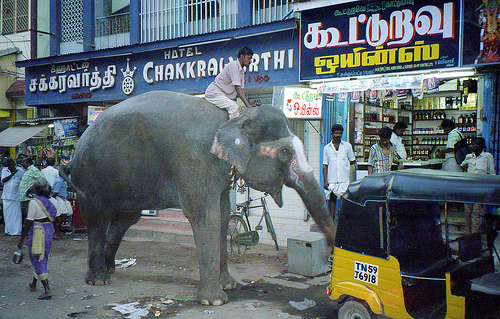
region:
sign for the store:
[304, 0, 461, 67]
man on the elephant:
[69, 35, 326, 301]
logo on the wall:
[20, 66, 225, 85]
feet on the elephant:
[186, 264, 251, 304]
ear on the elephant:
[196, 123, 251, 178]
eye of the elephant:
[277, 140, 303, 178]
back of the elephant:
[125, 86, 208, 113]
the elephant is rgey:
[185, 174, 221, 201]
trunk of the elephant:
[290, 186, 337, 238]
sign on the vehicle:
[350, 260, 384, 285]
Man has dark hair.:
[236, 45, 256, 65]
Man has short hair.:
[238, 46, 264, 68]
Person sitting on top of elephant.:
[182, 50, 253, 137]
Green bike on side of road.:
[222, 182, 290, 254]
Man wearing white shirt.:
[321, 148, 353, 174]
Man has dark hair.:
[327, 117, 347, 139]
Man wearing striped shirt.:
[368, 140, 396, 178]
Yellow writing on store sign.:
[325, 43, 428, 62]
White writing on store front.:
[31, 73, 166, 91]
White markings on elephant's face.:
[287, 131, 338, 201]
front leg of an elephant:
[172, 158, 229, 308]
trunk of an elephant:
[292, 142, 341, 264]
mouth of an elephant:
[270, 175, 299, 206]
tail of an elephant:
[56, 154, 92, 211]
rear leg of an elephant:
[73, 182, 118, 289]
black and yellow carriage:
[324, 168, 493, 316]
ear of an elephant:
[212, 114, 255, 176]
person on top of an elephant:
[207, 50, 258, 123]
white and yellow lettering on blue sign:
[302, 7, 470, 65]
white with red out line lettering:
[293, 7, 455, 74]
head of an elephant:
[210, 99, 310, 209]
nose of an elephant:
[295, 163, 356, 250]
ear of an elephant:
[180, 112, 248, 177]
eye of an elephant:
[269, 135, 297, 160]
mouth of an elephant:
[269, 171, 294, 202]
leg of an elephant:
[182, 211, 226, 309]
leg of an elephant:
[107, 203, 154, 277]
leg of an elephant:
[69, 211, 120, 283]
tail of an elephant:
[56, 173, 100, 195]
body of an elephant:
[65, 91, 200, 218]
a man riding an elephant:
[56, 47, 336, 307]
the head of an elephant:
[205, 99, 348, 260]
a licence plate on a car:
[348, 259, 380, 289]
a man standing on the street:
[317, 122, 354, 226]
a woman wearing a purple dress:
[10, 176, 59, 302]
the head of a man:
[232, 44, 256, 68]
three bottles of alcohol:
[455, 112, 478, 127]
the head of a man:
[326, 123, 346, 144]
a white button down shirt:
[319, 139, 355, 197]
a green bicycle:
[223, 197, 282, 261]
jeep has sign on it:
[351, 248, 392, 288]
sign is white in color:
[342, 253, 392, 285]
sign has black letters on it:
[343, 252, 396, 284]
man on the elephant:
[205, 29, 258, 151]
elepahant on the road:
[47, 49, 352, 299]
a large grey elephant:
[60, 90, 346, 305]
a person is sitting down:
[207, 51, 256, 114]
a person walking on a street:
[13, 172, 58, 298]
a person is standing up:
[317, 123, 353, 213]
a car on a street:
[319, 166, 498, 316]